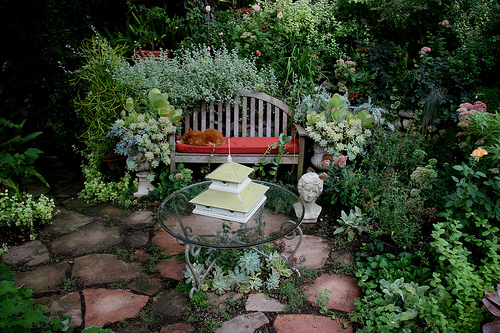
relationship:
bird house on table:
[186, 135, 268, 224] [156, 178, 303, 303]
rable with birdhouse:
[157, 180, 305, 300] [191, 144, 265, 224]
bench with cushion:
[169, 89, 308, 182] [172, 120, 297, 150]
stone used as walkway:
[68, 251, 153, 287] [13, 210, 360, 328]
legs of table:
[170, 196, 304, 286] [156, 165, 307, 299]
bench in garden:
[162, 82, 309, 193] [102, 8, 497, 331]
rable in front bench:
[157, 180, 305, 300] [169, 91, 304, 178]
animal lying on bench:
[177, 127, 227, 150] [169, 91, 304, 178]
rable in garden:
[157, 180, 305, 300] [11, 6, 498, 301]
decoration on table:
[186, 145, 273, 228] [148, 171, 313, 300]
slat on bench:
[232, 91, 251, 138] [173, 85, 303, 189]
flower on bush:
[466, 146, 488, 159] [353, 218, 498, 332]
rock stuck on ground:
[69, 285, 146, 329] [11, 175, 366, 331]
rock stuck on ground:
[211, 308, 268, 330] [11, 175, 366, 331]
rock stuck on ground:
[235, 284, 312, 320] [0, 192, 359, 331]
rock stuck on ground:
[277, 313, 335, 330] [286, 267, 336, 303]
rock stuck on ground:
[294, 266, 362, 313] [0, 192, 359, 331]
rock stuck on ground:
[109, 201, 151, 252] [0, 192, 359, 331]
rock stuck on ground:
[51, 230, 122, 263] [72, 252, 154, 319]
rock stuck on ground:
[39, 209, 92, 234] [11, 175, 366, 331]